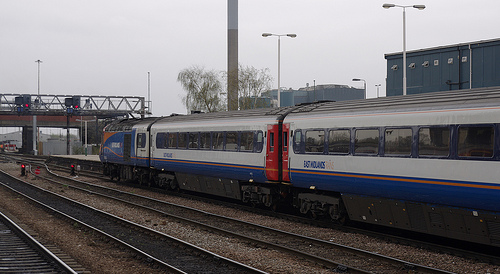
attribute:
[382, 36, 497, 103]
building — metal, dark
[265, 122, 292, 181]
doors — red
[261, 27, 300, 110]
tall/white lamp-posts — white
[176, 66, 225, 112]
tree — growing 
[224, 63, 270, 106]
tree — growing 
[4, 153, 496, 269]
tracks — metal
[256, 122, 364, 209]
doors — red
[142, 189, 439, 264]
railroad tracks — black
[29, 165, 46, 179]
sign — red, white, circular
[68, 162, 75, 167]
light — red, illuminated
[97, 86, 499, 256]
train — white, blue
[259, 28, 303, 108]
lamp posts — tall